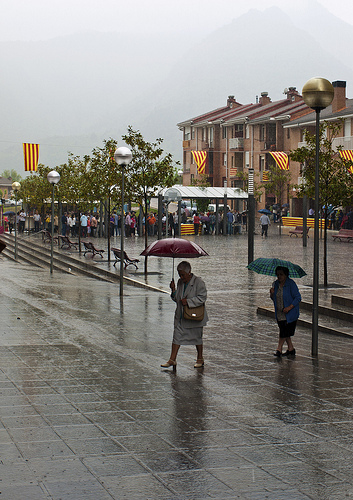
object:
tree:
[322, 143, 330, 287]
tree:
[140, 174, 148, 275]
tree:
[105, 188, 112, 263]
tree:
[75, 193, 83, 253]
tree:
[40, 196, 44, 241]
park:
[0, 171, 353, 500]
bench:
[111, 243, 132, 278]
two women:
[160, 260, 306, 370]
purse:
[181, 299, 205, 322]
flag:
[22, 139, 41, 178]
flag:
[267, 148, 289, 168]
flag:
[336, 148, 351, 176]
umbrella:
[136, 234, 209, 259]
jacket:
[169, 271, 210, 331]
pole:
[247, 161, 255, 272]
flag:
[187, 149, 215, 176]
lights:
[46, 169, 62, 189]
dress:
[170, 276, 207, 342]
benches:
[108, 246, 138, 275]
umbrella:
[256, 208, 273, 215]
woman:
[260, 214, 271, 235]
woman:
[7, 214, 13, 233]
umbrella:
[4, 210, 16, 214]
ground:
[260, 58, 311, 92]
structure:
[156, 183, 246, 236]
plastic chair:
[279, 275, 301, 325]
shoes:
[160, 358, 180, 367]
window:
[222, 153, 226, 166]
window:
[259, 154, 265, 181]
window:
[206, 126, 214, 141]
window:
[221, 126, 226, 138]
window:
[259, 124, 264, 140]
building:
[175, 79, 353, 229]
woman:
[268, 266, 302, 358]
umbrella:
[251, 256, 308, 281]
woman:
[159, 261, 208, 374]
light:
[112, 145, 132, 170]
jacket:
[263, 272, 307, 321]